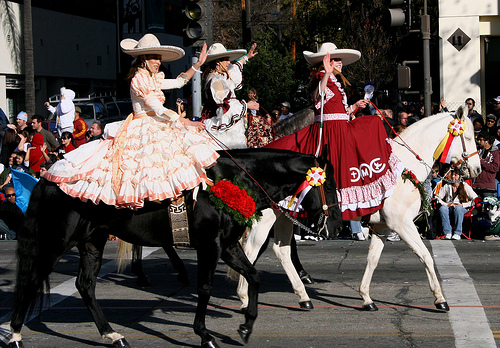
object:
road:
[0, 222, 500, 347]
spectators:
[469, 129, 500, 200]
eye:
[464, 136, 474, 141]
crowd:
[0, 84, 106, 246]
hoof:
[3, 340, 23, 347]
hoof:
[111, 334, 133, 347]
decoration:
[206, 177, 260, 226]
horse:
[235, 103, 483, 313]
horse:
[5, 142, 344, 346]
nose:
[473, 161, 483, 177]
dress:
[40, 66, 222, 215]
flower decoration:
[303, 163, 327, 189]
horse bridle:
[286, 174, 317, 214]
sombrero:
[117, 31, 189, 63]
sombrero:
[199, 41, 246, 65]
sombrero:
[300, 41, 363, 67]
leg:
[357, 214, 387, 297]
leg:
[381, 213, 446, 304]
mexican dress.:
[256, 69, 403, 221]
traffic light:
[180, 0, 216, 50]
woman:
[200, 42, 263, 149]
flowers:
[209, 178, 259, 219]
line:
[425, 239, 500, 347]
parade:
[0, 30, 486, 346]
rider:
[306, 41, 381, 223]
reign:
[201, 122, 288, 213]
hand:
[191, 120, 211, 133]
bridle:
[431, 116, 467, 165]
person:
[116, 40, 212, 205]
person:
[429, 168, 481, 241]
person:
[31, 114, 62, 153]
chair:
[431, 173, 482, 239]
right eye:
[325, 179, 334, 192]